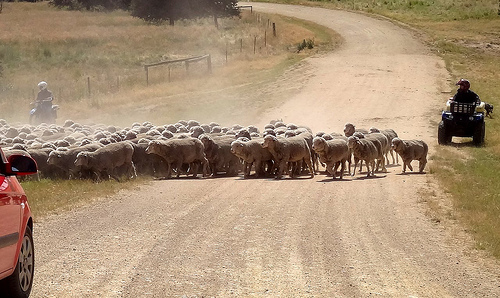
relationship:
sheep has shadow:
[310, 136, 352, 180] [320, 173, 348, 182]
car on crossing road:
[1, 139, 33, 293] [23, 0, 500, 298]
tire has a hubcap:
[1, 225, 36, 297] [16, 234, 33, 290]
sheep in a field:
[347, 136, 380, 176] [4, 11, 493, 296]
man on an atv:
[441, 76, 483, 109] [429, 107, 489, 150]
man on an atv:
[32, 74, 51, 119] [21, 94, 58, 119]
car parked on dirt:
[1, 139, 36, 297] [31, 150, 498, 297]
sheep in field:
[262, 133, 315, 179] [3, 5, 348, 219]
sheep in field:
[308, 135, 349, 177] [4, 11, 493, 296]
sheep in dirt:
[391, 135, 431, 174] [33, 3, 491, 294]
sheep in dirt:
[347, 136, 380, 176] [33, 3, 491, 294]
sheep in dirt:
[261, 131, 313, 176] [33, 3, 491, 294]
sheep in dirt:
[229, 131, 259, 169] [33, 3, 491, 294]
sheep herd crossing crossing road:
[8, 110, 428, 193] [23, 0, 500, 298]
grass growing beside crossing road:
[456, 156, 498, 247] [23, 0, 500, 298]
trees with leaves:
[65, 1, 237, 25] [54, 1, 246, 26]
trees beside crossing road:
[65, 1, 237, 25] [23, 0, 500, 298]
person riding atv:
[442, 78, 484, 108] [21, 94, 61, 125]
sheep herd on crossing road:
[0, 118, 428, 182] [23, 0, 500, 298]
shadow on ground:
[397, 167, 439, 182] [3, 0, 497, 294]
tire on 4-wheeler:
[434, 116, 458, 150] [426, 75, 495, 166]